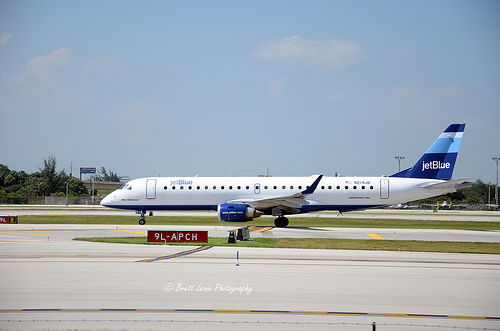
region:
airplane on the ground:
[60, 62, 468, 295]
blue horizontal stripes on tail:
[385, 86, 465, 196]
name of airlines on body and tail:
[150, 150, 475, 200]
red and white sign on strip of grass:
[120, 220, 475, 265]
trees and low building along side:
[5, 151, 115, 206]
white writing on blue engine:
[211, 195, 266, 226]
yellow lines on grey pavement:
[10, 220, 392, 275]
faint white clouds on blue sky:
[35, 17, 415, 109]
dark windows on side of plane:
[130, 172, 375, 192]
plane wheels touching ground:
[102, 200, 314, 236]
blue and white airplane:
[82, 112, 486, 245]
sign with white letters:
[134, 223, 211, 250]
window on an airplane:
[367, 181, 377, 192]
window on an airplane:
[357, 182, 367, 192]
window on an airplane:
[348, 183, 358, 192]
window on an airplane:
[342, 181, 349, 191]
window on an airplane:
[332, 181, 343, 193]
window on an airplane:
[327, 181, 334, 192]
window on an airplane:
[162, 180, 171, 193]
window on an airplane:
[183, 178, 193, 192]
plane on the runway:
[61, 93, 481, 298]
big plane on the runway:
[76, 94, 471, 276]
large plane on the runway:
[45, 66, 473, 275]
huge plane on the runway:
[72, 83, 483, 285]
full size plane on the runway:
[51, 80, 469, 307]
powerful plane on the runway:
[64, 71, 468, 299]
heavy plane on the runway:
[56, 76, 478, 284]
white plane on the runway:
[57, 77, 482, 279]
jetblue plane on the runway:
[85, 44, 476, 282]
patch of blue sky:
[37, 13, 413, 129]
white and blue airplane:
[98, 124, 469, 226]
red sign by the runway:
[146, 228, 208, 244]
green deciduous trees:
[1, 157, 87, 197]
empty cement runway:
[7, 250, 494, 322]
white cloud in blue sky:
[243, 26, 392, 98]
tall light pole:
[490, 154, 499, 209]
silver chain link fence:
[3, 194, 98, 204]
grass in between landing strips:
[265, 237, 496, 254]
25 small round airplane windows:
[162, 183, 377, 190]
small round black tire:
[136, 215, 146, 227]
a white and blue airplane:
[90, 110, 476, 244]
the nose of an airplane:
[95, 190, 115, 214]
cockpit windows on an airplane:
[117, 178, 135, 191]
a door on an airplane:
[143, 173, 160, 202]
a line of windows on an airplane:
[163, 176, 252, 196]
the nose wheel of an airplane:
[132, 214, 148, 226]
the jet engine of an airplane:
[214, 194, 267, 228]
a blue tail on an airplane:
[391, 115, 473, 190]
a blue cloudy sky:
[6, 0, 498, 189]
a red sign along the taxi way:
[141, 222, 216, 249]